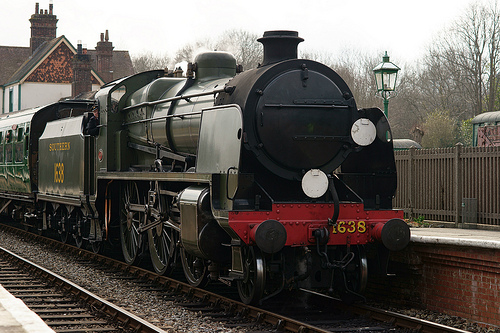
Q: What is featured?
A: A train.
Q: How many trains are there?
A: One.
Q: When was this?
A: Daytime.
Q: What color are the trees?
A: Green.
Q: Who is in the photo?
A: No one.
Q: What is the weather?
A: Cloudy.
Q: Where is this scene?
A: Railway.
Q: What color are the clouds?
A: Grey.